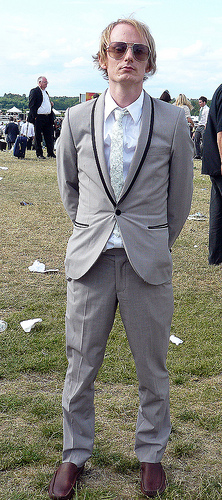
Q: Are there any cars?
A: No, there are no cars.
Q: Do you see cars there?
A: No, there are no cars.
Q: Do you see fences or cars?
A: No, there are no cars or fences.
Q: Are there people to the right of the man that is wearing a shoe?
A: Yes, there are people to the right of the man.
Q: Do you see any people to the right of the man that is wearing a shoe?
A: Yes, there are people to the right of the man.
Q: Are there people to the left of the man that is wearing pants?
A: No, the people are to the right of the man.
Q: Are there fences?
A: No, there are no fences.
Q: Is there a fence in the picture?
A: No, there are no fences.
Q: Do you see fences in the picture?
A: No, there are no fences.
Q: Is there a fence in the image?
A: No, there are no fences.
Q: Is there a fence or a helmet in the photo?
A: No, there are no fences or helmets.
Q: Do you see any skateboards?
A: No, there are no skateboards.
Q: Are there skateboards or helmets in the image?
A: No, there are no skateboards or helmets.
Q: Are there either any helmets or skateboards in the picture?
A: No, there are no skateboards or helmets.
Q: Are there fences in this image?
A: No, there are no fences.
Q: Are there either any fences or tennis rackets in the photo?
A: No, there are no fences or tennis rackets.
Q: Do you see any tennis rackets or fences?
A: No, there are no fences or tennis rackets.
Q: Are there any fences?
A: No, there are no fences.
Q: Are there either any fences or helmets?
A: No, there are no fences or helmets.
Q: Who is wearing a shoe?
A: The man is wearing a shoe.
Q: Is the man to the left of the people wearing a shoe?
A: Yes, the man is wearing a shoe.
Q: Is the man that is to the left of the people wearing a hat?
A: No, the man is wearing a shoe.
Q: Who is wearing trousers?
A: The man is wearing trousers.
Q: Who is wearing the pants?
A: The man is wearing trousers.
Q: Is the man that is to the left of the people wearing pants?
A: Yes, the man is wearing pants.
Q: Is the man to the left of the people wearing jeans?
A: No, the man is wearing pants.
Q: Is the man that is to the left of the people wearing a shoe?
A: Yes, the man is wearing a shoe.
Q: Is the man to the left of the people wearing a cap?
A: No, the man is wearing a shoe.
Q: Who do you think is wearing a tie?
A: The man is wearing a tie.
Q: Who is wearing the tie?
A: The man is wearing a tie.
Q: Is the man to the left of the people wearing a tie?
A: Yes, the man is wearing a tie.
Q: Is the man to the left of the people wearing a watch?
A: No, the man is wearing a tie.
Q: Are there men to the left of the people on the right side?
A: Yes, there is a man to the left of the people.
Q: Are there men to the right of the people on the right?
A: No, the man is to the left of the people.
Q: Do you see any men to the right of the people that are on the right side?
A: No, the man is to the left of the people.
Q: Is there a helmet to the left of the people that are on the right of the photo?
A: No, there is a man to the left of the people.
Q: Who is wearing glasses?
A: The man is wearing glasses.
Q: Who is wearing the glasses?
A: The man is wearing glasses.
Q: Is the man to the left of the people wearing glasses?
A: Yes, the man is wearing glasses.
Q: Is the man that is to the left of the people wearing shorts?
A: No, the man is wearing glasses.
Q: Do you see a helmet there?
A: No, there are no helmets.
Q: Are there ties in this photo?
A: Yes, there is a tie.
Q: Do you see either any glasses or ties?
A: Yes, there is a tie.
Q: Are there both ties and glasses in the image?
A: Yes, there are both a tie and glasses.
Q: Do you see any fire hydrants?
A: No, there are no fire hydrants.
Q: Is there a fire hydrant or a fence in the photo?
A: No, there are no fire hydrants or fences.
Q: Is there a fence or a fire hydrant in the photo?
A: No, there are no fire hydrants or fences.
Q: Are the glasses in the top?
A: Yes, the glasses are in the top of the image.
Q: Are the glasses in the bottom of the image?
A: No, the glasses are in the top of the image.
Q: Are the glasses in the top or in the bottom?
A: The glasses are in the top of the image.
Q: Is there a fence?
A: No, there are no fences.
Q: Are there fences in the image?
A: No, there are no fences.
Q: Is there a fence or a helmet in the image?
A: No, there are no fences or helmets.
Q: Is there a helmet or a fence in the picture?
A: No, there are no fences or helmets.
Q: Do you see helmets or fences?
A: No, there are no fences or helmets.